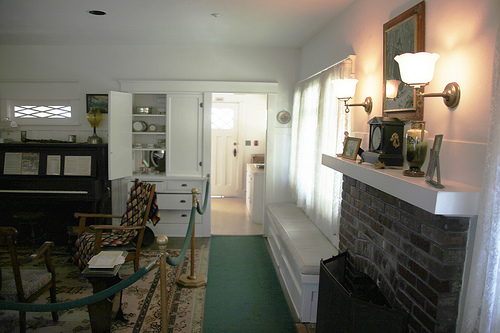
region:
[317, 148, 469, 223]
a white fireplace mantle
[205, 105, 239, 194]
part of a white door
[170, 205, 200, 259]
a long green rope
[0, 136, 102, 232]
part of a large piano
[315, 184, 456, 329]
a brick fireplace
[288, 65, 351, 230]
large white window curtains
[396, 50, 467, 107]
a wall lamp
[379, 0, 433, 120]
a large brown picture frame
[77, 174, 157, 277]
a brown rocking chair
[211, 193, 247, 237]
white kitchen floor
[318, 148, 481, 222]
white fireplace mantle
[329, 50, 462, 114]
white and bronze lights hanging above the fireplace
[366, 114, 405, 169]
old brown and white clock sitting on the fireplace mantle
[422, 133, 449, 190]
picture frame on the fireplace mantle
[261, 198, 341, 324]
white window bench with cushion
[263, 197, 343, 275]
white cushion on the window bench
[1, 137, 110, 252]
brown piano and stool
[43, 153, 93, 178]
piano sheet music on the piano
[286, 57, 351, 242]
white curtains on the window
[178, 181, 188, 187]
black handle on the white drawer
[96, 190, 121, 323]
There is a chair that is visible here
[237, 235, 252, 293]
There is a turquoise runner here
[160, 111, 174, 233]
There is a white cabinet that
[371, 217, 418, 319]
There is brown brick here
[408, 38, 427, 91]
There is a lamp that is visible here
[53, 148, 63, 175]
There is a sheet of music here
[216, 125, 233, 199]
There is a white door that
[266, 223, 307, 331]
There is a white chest that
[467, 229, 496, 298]
There is a white curtain that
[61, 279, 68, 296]
There is a large rug that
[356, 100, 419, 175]
clock on mantle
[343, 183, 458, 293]
fireplace made of brick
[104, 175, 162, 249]
checked blanket on chair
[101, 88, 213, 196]
cupboard with open door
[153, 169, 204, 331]
barrier with green rope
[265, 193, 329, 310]
white seat cushion on window seat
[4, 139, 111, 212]
sheet music on piano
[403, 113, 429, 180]
vase on mantle top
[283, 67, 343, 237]
white curtains covering large window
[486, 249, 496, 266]
part of a curtain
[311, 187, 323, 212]
part of a window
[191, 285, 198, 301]
part of a carpet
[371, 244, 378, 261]
part of a wall